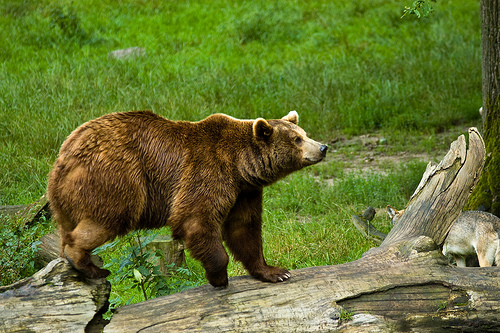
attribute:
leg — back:
[52, 215, 140, 311]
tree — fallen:
[0, 127, 499, 332]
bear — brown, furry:
[39, 99, 336, 290]